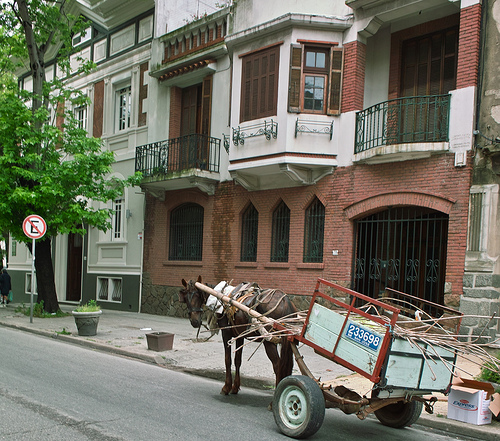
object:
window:
[296, 193, 329, 271]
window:
[263, 193, 293, 268]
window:
[232, 198, 260, 268]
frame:
[122, 183, 127, 240]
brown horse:
[176, 273, 301, 402]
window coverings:
[313, 244, 320, 251]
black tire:
[270, 372, 328, 439]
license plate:
[344, 322, 383, 353]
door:
[54, 220, 85, 306]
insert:
[65, 230, 83, 302]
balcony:
[123, 128, 232, 193]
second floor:
[130, 10, 352, 203]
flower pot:
[71, 305, 103, 337]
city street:
[0, 291, 500, 440]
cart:
[268, 272, 466, 441]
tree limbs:
[418, 330, 433, 338]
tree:
[0, 0, 130, 318]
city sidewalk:
[1, 319, 500, 441]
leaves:
[49, 170, 60, 185]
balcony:
[351, 93, 451, 166]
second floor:
[331, 0, 483, 170]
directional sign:
[19, 212, 49, 241]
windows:
[236, 39, 284, 124]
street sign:
[20, 211, 49, 240]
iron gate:
[341, 187, 461, 335]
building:
[323, 0, 486, 353]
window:
[106, 62, 136, 140]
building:
[0, 0, 194, 314]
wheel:
[270, 372, 329, 440]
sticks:
[447, 347, 461, 358]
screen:
[179, 85, 198, 169]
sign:
[20, 212, 47, 325]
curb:
[0, 319, 500, 441]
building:
[130, 0, 344, 337]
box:
[447, 375, 500, 428]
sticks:
[417, 307, 426, 315]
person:
[0, 264, 12, 306]